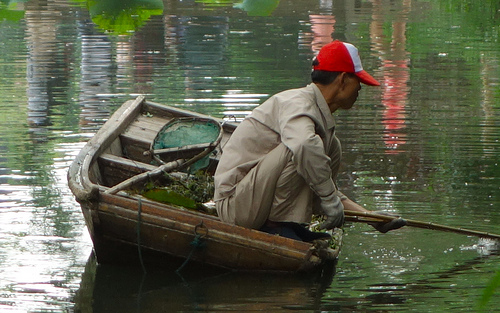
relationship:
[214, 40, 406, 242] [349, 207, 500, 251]
man standing with net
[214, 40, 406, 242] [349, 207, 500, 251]
man holding net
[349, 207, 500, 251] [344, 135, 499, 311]
net in water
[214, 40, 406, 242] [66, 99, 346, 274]
man has boat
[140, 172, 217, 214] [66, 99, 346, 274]
plants are in boat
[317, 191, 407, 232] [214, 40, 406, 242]
gloves are worn by man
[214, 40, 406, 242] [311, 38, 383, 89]
man has baseball cap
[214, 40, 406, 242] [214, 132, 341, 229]
man has pants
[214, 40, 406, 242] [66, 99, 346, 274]
man on boat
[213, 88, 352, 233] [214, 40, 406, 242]
suit on man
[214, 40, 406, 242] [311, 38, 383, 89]
man has hat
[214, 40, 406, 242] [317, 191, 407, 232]
man has gloves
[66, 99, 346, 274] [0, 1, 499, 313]
boat in water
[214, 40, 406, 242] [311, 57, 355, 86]
man has hair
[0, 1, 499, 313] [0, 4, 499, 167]
water has shadow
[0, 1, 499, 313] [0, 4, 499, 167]
water has reflections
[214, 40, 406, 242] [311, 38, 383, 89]
man wearing cap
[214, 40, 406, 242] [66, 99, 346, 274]
man sitting in a boat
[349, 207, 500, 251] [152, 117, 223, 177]
net for fishing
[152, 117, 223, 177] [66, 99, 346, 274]
fishing in boat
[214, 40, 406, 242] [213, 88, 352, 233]
man wearing clothing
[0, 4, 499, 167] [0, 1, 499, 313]
reflections are on water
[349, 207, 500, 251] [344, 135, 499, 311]
net dunked in water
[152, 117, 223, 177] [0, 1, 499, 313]
net out of water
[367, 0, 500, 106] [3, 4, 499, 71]
reflections are of plants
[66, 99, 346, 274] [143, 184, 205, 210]
boat has leaf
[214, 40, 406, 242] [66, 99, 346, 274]
man i boat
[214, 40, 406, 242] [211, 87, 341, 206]
man has shirt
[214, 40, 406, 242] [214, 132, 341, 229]
man has worn pants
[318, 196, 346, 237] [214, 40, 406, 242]
glove worn by man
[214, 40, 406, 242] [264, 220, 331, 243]
man has shoes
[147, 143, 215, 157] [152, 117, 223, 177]
stick in net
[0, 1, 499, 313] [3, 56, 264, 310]
pond reflecting light